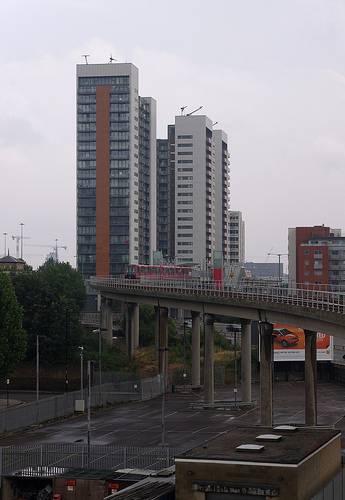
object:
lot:
[184, 411, 236, 435]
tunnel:
[2, 465, 55, 500]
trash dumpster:
[99, 467, 157, 500]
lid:
[235, 443, 265, 453]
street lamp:
[36, 334, 47, 427]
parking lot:
[0, 390, 239, 474]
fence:
[0, 445, 42, 480]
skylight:
[254, 434, 283, 442]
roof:
[174, 424, 343, 468]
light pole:
[161, 346, 166, 444]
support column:
[303, 329, 318, 426]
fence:
[141, 375, 163, 403]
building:
[75, 62, 139, 332]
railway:
[142, 283, 345, 316]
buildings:
[287, 223, 331, 298]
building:
[171, 426, 343, 500]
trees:
[0, 266, 29, 388]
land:
[36, 407, 173, 450]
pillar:
[203, 314, 214, 410]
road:
[213, 322, 242, 340]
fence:
[82, 445, 126, 471]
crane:
[23, 239, 67, 263]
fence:
[2, 400, 38, 438]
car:
[272, 327, 300, 347]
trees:
[38, 294, 87, 367]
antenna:
[82, 53, 91, 65]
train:
[124, 263, 195, 286]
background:
[168, 313, 206, 363]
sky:
[210, 5, 345, 129]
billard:
[257, 321, 334, 363]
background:
[213, 320, 256, 360]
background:
[80, 306, 126, 352]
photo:
[0, 0, 345, 500]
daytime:
[0, 0, 345, 292]